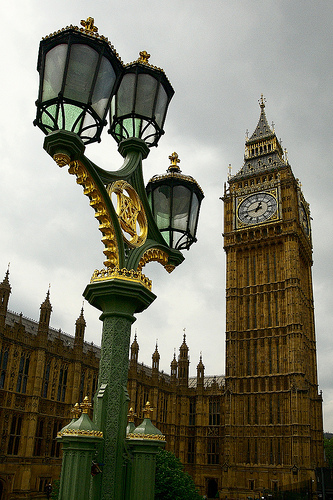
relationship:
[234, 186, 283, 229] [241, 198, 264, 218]
clock has hands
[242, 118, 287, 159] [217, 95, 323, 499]
crosses on building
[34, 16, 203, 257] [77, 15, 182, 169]
lights have crosses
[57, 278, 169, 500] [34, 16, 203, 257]
pole under lights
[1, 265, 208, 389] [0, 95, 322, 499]
spires on building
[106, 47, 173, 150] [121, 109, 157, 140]
light has bulbs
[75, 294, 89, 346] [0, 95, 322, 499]
steeple on building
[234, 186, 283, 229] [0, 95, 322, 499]
clock on building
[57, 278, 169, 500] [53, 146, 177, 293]
pole has decorations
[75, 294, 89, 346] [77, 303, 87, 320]
steeple has point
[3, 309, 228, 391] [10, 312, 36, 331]
roof has spikes